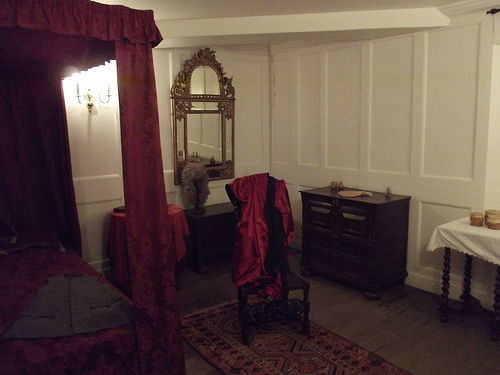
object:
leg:
[491, 265, 500, 340]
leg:
[439, 247, 451, 322]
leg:
[459, 254, 473, 315]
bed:
[0, 234, 139, 375]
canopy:
[0, 0, 163, 79]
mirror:
[176, 66, 233, 168]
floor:
[378, 304, 436, 355]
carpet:
[179, 294, 410, 374]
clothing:
[229, 173, 295, 304]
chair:
[224, 172, 310, 344]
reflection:
[177, 114, 219, 171]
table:
[437, 215, 500, 341]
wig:
[181, 162, 210, 205]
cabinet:
[182, 202, 236, 274]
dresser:
[298, 185, 411, 301]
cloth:
[127, 216, 176, 300]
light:
[98, 68, 118, 104]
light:
[69, 72, 87, 106]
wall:
[61, 0, 500, 310]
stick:
[440, 248, 451, 322]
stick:
[491, 266, 500, 341]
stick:
[460, 253, 472, 310]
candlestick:
[76, 83, 111, 111]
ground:
[174, 246, 499, 375]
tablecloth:
[426, 217, 500, 266]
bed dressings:
[0, 0, 183, 375]